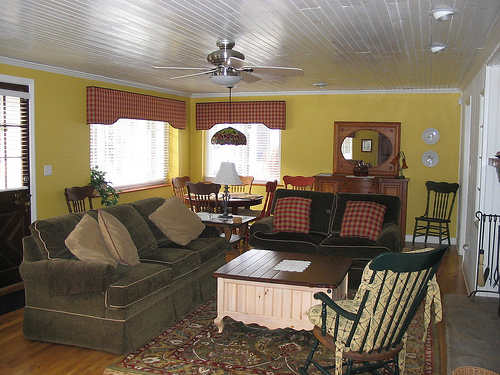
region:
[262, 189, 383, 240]
two red and white cushions on a black couch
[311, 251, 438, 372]
a black rocking chair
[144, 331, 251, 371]
a colorful Turkish carpet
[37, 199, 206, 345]
a comfortable brown couch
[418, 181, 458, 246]
a wooden chair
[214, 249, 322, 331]
a wooden coffee table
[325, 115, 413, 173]
a wooden mirror on the yellow wall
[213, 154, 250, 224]
a white lamp on a table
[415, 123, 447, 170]
two decorative plates on a wall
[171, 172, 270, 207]
a wooden table with four chairs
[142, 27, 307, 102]
Fan on the ceiling.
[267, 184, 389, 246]
Two pillows on the couch.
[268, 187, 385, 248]
The pillows are plaid.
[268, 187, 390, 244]
The pillows are red.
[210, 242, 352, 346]
The table is wooden.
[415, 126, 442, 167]
Plates on the wall.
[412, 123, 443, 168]
The plates are white.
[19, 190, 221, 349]
The couch is brown.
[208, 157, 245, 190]
Lamp shade is white.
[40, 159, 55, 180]
Light switch is white.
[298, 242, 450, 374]
Rocking chair in the living room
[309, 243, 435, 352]
Cushion on the rocking chair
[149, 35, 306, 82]
Fan hanging from the ceiling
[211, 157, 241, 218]
Light on the stand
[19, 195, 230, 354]
brown couch in the living room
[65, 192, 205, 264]
Pillows on the couch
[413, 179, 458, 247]
Chair in the corner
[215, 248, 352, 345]
Coffee table on the rug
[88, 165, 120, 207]
Plant on the window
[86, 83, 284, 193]
Windows on the wall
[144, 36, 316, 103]
A fan is hanging from a ceiling.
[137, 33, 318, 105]
A fan's colors are silver and white.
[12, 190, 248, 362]
A couches color is olive-green.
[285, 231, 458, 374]
A rocking chair's colors are green and brown.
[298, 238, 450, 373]
A chair is holding two cushions.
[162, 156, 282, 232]
A table is in the background.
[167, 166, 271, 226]
A table's color is brown.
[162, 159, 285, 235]
Four chairs are sitting around a table.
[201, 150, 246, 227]
A white lamp is sitting on a table.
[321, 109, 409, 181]
A mirror is in the background.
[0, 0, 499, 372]
cozy living space with furniture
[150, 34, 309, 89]
a wooden ceiling fan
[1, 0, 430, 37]
polished wood ceiling in room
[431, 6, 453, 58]
partially recessed lighting in room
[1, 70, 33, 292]
wooden living room door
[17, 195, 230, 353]
plush brown couch with pillows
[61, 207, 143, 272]
tan throw pillows on couch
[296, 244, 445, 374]
padded rocking chair in living room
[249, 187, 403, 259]
dark brown couch with pillows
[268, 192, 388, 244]
plaid throw pillows on couch